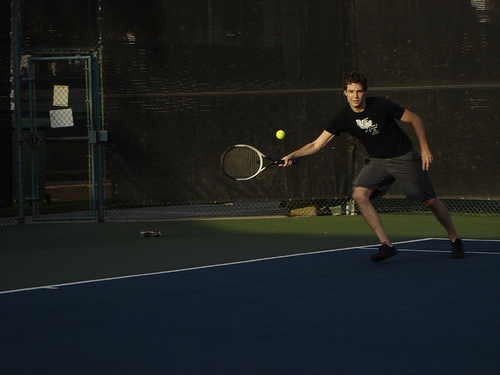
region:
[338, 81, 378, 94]
boy has brown hair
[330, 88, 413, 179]
black and white shirt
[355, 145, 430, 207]
boy has grey shorts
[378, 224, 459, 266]
boy has black shoes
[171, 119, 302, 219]
black and white racket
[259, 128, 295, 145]
yellow ball near racket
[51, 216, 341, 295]
white line on court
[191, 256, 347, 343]
court is dark blue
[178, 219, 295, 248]
court is light green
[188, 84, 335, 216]
grey fence behind boy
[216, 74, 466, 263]
The man plays tennis.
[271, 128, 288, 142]
The ball is airborne.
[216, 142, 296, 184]
The man holds a racquet.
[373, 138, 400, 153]
The shirt is black.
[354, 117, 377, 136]
A graphic is on the shirt.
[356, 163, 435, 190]
The man wears shorts.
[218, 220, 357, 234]
Sunlight shines on the court.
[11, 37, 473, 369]
A person is on a tennis court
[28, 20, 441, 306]
A person is playing a game of tennis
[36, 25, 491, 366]
A person is wearing nice shorts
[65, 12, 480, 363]
A person is holding a tennis racket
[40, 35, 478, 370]
A person is getting some exercise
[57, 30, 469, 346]
A person has dark colored hair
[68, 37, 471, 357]
The person is a full grown male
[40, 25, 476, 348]
The person is having some fun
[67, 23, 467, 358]
The person is out in the daytime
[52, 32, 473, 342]
The person is enjoying the day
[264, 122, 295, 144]
green ball in air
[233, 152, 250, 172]
inside of tennis racket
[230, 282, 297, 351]
blue color on court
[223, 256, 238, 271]
white line on court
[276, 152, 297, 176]
man hand on racket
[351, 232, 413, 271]
man wearing black sneakers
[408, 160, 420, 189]
man wearing grey shorts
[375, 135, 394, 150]
man wearing black shirt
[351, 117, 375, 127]
white symbol on shirt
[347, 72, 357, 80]
man has short hair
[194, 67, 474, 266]
the person playing tennis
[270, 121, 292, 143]
the ball in the air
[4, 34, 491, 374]
tennis court has a fence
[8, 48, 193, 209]
door on side a fence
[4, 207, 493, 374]
tennis court is green and purple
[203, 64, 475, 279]
tennis player hitting a ball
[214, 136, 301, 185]
racket is black and white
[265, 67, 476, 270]
player wears black shirt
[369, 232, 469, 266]
shoes are color black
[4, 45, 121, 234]
the door is made of metal